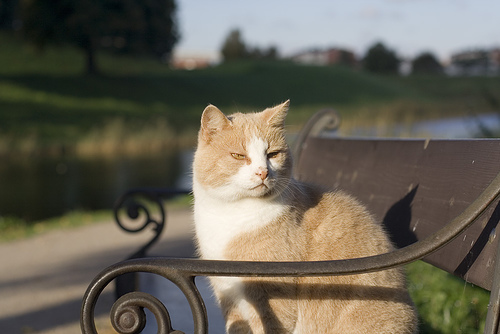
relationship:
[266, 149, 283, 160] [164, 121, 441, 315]
eye of cat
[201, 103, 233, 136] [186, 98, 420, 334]
ear of cat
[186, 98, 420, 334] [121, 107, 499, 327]
cat in bench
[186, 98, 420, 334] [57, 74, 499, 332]
cat on bench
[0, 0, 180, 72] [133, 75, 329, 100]
tree on grass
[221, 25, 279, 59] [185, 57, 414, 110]
trees on hill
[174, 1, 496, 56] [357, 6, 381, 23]
sky with cloud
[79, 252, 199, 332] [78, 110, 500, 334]
arm of bench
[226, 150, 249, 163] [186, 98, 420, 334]
eye of cat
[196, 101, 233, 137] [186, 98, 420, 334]
ear of cat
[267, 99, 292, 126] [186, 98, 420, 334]
ear of cat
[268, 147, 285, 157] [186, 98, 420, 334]
eye of cat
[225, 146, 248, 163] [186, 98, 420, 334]
eye of cat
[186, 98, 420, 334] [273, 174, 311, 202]
cat has whiskers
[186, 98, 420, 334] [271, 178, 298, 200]
cat has whisker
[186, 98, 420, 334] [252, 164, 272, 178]
cat has nose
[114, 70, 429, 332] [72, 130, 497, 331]
cat on bench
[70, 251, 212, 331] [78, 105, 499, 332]
design on bench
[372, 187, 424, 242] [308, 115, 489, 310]
shadow on bench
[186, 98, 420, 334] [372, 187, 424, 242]
cat has shadow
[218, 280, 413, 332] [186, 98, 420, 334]
shadow on cat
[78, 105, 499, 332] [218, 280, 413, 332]
bench has shadow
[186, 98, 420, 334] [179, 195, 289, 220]
cat has neck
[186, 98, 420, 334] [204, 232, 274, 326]
cat has belly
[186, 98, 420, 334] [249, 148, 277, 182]
cat has nose